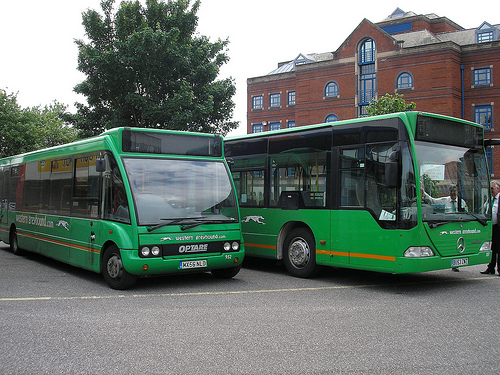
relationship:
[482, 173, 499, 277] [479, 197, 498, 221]
man wears tie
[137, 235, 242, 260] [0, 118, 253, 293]
lights are on bus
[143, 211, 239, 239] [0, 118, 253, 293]
windshield wipers are on bus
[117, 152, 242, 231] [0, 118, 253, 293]
windshield on bus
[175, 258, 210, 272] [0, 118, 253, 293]
license tag on bus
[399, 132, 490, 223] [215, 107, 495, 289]
window on right bus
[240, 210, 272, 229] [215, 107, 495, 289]
greyhound embleg on right bus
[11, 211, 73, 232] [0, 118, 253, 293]
symbol on bus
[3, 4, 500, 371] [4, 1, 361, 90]
photo was taken in daylight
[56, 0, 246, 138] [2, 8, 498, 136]
tree in background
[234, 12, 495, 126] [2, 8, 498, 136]
buildings are in background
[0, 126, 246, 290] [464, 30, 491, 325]
bus are facing in same direction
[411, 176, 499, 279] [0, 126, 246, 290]
two men are near bus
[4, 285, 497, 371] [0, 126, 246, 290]
pavement has bus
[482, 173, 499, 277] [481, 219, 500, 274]
man has black pants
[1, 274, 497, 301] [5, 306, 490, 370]
line on ground